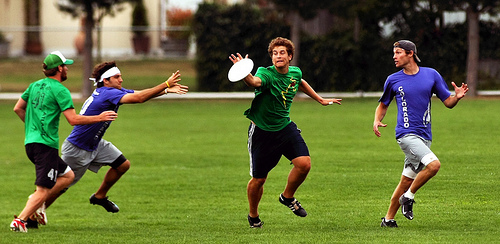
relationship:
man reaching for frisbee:
[228, 37, 342, 226] [228, 58, 253, 83]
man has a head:
[228, 37, 342, 226] [267, 37, 295, 69]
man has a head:
[27, 60, 190, 230] [91, 61, 123, 91]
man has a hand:
[228, 37, 342, 226] [321, 96, 343, 107]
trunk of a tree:
[464, 15, 479, 98] [429, 1, 500, 97]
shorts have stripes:
[246, 121, 311, 179] [247, 123, 256, 176]